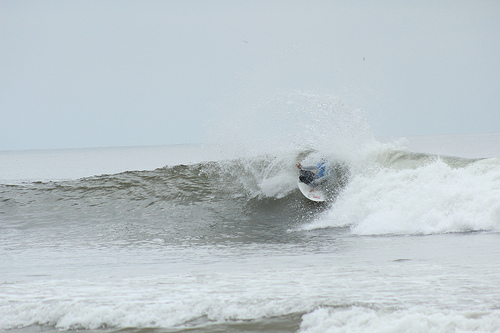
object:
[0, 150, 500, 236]
waves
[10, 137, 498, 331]
water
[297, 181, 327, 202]
surfboard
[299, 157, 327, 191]
surfer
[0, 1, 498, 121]
sky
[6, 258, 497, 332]
foamy water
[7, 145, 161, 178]
calm waters